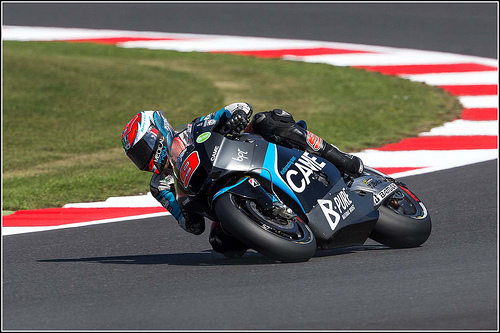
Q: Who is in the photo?
A: A racer.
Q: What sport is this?
A: Motor racing.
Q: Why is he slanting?
A: To make a corner.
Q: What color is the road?
A: Grey.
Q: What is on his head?
A: Helmet.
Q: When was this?
A: Daytime.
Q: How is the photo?
A: Clear.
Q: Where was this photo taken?
A: At the racetrack.